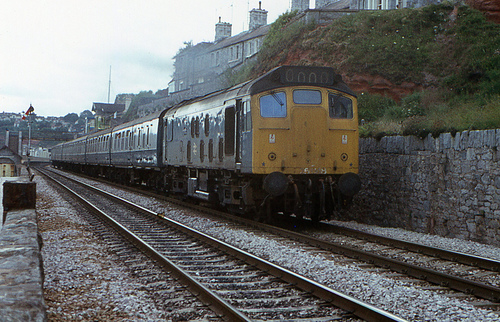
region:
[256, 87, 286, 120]
the windshield of a train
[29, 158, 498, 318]
two sets of train tracks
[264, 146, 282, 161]
a headlight on the train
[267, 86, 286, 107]
a black windshield wiper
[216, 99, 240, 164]
the door of a train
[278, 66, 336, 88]
numbers on the front of the train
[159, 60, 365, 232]
a yellow train engine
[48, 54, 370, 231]
a long train on the tracks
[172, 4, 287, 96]
a gray building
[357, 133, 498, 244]
a gray stone wall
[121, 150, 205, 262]
The railroad is visible.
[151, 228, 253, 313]
The railroad is visible.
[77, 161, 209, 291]
The railroad is visible.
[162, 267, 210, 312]
The railroad is visible.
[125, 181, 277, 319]
The railroad is visible.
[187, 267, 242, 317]
The railroad is visible.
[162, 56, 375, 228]
Front of train engine is yellow.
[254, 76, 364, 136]
Three small windows on front of train.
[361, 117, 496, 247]
High rock wall to right of train.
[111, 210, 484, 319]
Two sets of train tracks.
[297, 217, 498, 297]
Cross ties on right side tracks.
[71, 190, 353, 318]
Cross ties on left side tracks.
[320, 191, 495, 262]
Gravel on right side of tracks.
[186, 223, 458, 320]
Gravel in the middle of tracks.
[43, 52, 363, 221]
Five train cars.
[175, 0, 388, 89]
Stone building on top of hill.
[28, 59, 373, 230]
long shiny train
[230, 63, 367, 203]
yellow face of a train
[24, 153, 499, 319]
train tracks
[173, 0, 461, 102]
large buildings on the hill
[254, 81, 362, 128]
three windows in the front of the train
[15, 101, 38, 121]
flags flying in the distance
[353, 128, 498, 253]
gray stone work wall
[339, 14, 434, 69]
small white flowers on the hill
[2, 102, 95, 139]
buildings in the distance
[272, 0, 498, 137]
green grass growing on the hill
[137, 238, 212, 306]
The railroad is visible.